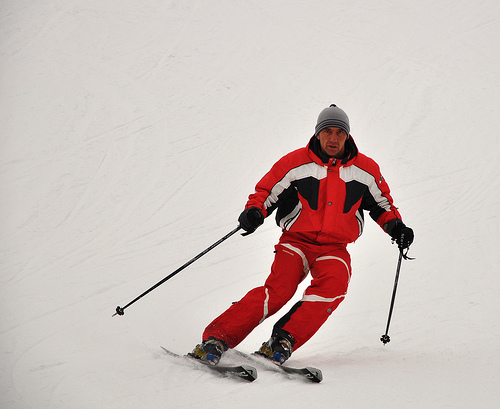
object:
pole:
[111, 225, 241, 316]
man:
[192, 102, 414, 363]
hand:
[236, 207, 263, 232]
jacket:
[285, 145, 375, 241]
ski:
[162, 339, 266, 391]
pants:
[202, 230, 350, 368]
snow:
[1, 0, 499, 406]